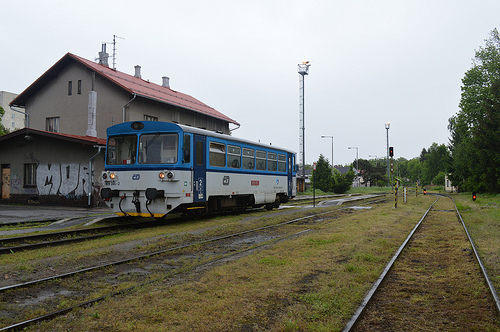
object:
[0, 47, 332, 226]
station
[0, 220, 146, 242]
train tracks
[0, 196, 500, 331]
foreground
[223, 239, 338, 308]
grass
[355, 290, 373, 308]
wet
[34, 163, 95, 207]
graffiti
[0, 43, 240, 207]
building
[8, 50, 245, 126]
roof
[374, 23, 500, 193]
trees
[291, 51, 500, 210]
background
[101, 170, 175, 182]
headlights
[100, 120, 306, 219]
train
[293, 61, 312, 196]
tower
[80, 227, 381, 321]
tracks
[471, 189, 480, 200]
signal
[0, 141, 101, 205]
wall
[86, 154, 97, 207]
water drain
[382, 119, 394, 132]
street lamp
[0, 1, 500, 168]
sky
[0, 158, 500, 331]
ground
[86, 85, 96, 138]
chimney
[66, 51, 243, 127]
rooftop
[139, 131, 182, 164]
window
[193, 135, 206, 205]
door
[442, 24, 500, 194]
tree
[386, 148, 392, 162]
traffic light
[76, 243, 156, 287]
mud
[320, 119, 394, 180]
streetlights